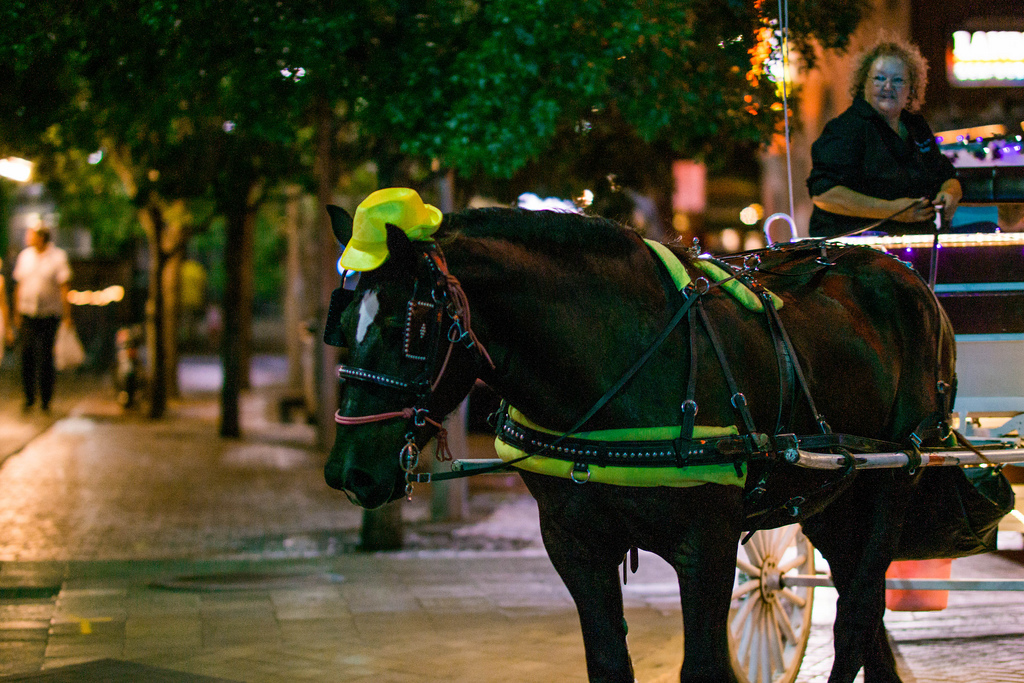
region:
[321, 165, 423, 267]
The hat on the horse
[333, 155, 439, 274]
A hat on the horse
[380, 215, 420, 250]
The right ear of the horse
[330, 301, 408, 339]
The eyes of the horse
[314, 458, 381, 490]
The nose of the horse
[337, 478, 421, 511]
The mouth of the horse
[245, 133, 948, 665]
A brown horse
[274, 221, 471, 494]
The face of the horse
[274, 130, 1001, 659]
this is a horse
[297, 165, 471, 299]
the horse is green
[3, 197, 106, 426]
person on the sidewalk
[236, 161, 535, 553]
bridle on the horse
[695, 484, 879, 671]
wheel on a carriage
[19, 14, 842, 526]
a row of trees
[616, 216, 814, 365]
green trim on straps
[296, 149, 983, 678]
Horse wearing a green hat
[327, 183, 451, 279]
green hat on a horse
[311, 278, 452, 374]
Blinders on the horse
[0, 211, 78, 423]
Person walking down the street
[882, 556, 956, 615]
Orange container on the street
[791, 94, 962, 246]
Black shirt on woman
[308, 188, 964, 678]
Brown healthy horse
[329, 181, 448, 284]
Small yellow hat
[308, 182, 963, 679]
Horse wearing yellow hat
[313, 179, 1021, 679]
Brown horse pulling carriage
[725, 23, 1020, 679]
Woman sitting on a carriage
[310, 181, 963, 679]
Horse has eye blinders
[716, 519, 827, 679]
White carriage wheel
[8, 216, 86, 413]
Person is walking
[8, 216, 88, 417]
Person carrying white plastic bag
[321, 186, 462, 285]
yellow hat on the horse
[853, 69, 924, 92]
woman is wearing reading glasses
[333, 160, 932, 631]
black horse pulling wagon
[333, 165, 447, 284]
yellow hat on black horse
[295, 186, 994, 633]
horse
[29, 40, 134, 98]
green leaves in brown tres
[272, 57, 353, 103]
green leaves in brown tres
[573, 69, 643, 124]
green leaves in brown tres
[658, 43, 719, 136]
green leaves in brown tres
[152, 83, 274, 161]
green leaves in brown tres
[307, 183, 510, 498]
the horse is wearing a yellow hat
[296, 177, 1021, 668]
the horse is pulling a carriage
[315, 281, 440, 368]
the horse has blinders on its head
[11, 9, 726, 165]
the tree has green leaves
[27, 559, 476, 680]
grey stone tiles on a walkway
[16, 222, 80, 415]
the man is wearing black pants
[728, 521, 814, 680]
the spokes on the wheel are white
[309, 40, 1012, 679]
horse pulling a carriage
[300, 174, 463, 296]
horse wearing a hat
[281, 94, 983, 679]
the horse is brown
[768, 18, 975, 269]
woman in the carriage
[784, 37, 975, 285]
woman holding the reigns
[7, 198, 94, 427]
man in the background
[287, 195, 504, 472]
bridle on the horse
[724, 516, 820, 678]
wheel on the carriage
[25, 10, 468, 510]
a row of trees